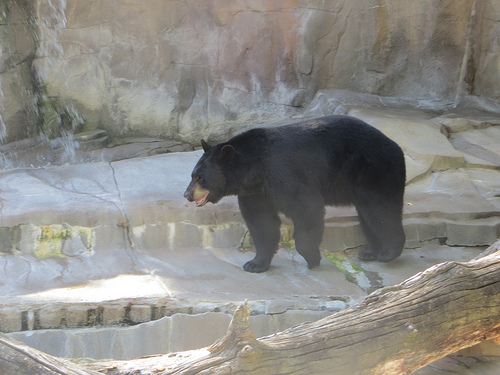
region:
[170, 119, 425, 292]
Large black bear on the pavement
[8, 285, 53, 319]
Small bumps on the concrete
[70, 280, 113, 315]
Small bumps on the concrete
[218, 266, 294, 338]
Small bumps on the concrete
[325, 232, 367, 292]
Small bumps on the concrete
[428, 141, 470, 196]
Small bumps on the concrete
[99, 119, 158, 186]
Small bumps on the concrete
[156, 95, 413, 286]
A large black bear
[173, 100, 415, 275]
A large bear that is walking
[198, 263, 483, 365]
Large wooden log of a tree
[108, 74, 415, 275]
The bear is walking on a stone surface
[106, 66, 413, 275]
The black bear is walking on a stone surface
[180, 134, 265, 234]
The bear's mouth is open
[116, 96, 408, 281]
The bear is walking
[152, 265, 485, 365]
Large log from a tree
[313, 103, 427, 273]
The rear of a bear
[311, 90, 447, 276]
The rear of the black bear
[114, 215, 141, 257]
a crack in rock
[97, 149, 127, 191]
a crack in rock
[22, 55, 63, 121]
a crack in rock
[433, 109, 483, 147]
a crack in rock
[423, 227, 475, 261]
a crack in rock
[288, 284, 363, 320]
a crack in rock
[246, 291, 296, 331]
a crack in rock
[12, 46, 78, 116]
a crack in rock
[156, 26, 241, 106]
a crack in rock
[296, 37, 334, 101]
a crack in rock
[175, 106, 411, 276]
a black bear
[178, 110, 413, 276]
black bear walking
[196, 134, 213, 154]
ear of the bear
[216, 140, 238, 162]
ear of the bear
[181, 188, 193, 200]
nose of the bear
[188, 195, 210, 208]
mouth of bear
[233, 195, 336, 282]
two front legs of bear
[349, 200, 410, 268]
two back legs of the bear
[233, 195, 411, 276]
four legs of the bear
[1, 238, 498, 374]
trunk of tree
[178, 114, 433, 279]
a black bear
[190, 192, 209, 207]
the pink tongue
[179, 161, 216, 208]
the face of bear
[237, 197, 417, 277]
the short legs of bear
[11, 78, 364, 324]
the moss on the rocks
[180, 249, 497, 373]
the long log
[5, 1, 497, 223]
the rock wall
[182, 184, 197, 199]
the nose on head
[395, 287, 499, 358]
the green on log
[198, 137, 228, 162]
ears of bear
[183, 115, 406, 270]
black bear in cave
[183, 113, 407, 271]
bear walking on rock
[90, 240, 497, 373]
branc on top of rock